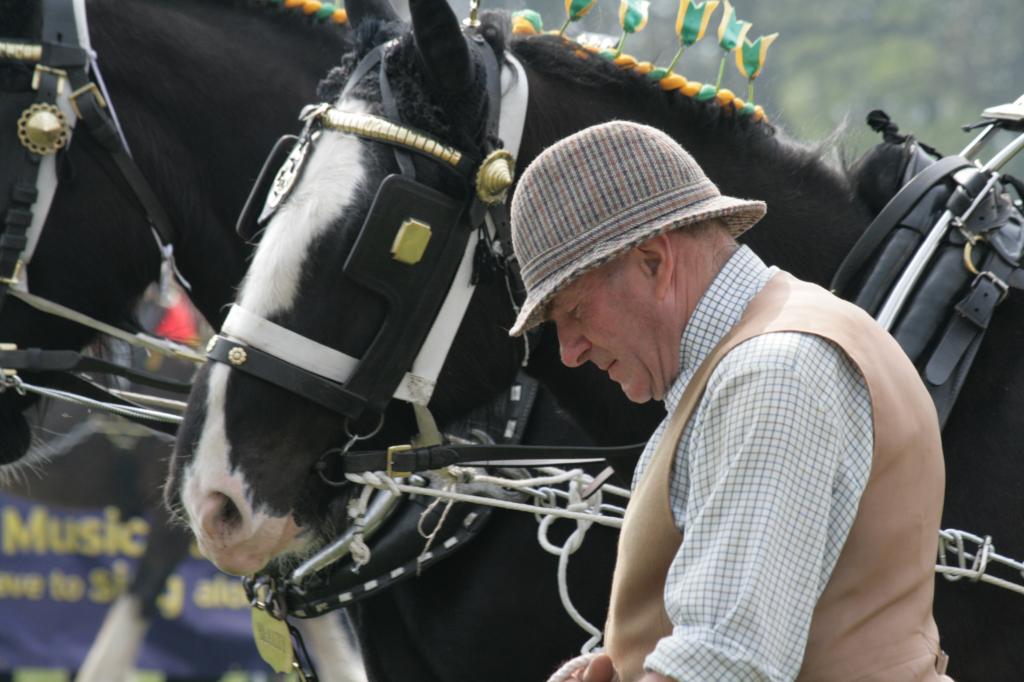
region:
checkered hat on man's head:
[502, 122, 763, 326]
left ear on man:
[632, 226, 677, 297]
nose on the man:
[546, 322, 594, 370]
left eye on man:
[555, 298, 597, 328]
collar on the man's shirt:
[667, 248, 772, 372]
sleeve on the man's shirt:
[654, 331, 882, 680]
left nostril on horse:
[182, 476, 253, 533]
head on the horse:
[152, 3, 552, 589]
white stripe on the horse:
[151, 109, 376, 506]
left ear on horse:
[403, 0, 476, 78]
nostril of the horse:
[193, 491, 258, 537]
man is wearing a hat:
[515, 141, 684, 249]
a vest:
[848, 551, 943, 676]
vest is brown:
[603, 548, 658, 602]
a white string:
[532, 494, 602, 558]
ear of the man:
[638, 238, 683, 286]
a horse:
[6, 20, 225, 296]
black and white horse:
[163, 1, 884, 676]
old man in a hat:
[508, 121, 954, 675]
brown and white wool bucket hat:
[498, 117, 790, 336]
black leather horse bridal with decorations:
[189, 10, 538, 432]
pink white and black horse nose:
[144, 376, 364, 618]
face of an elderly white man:
[543, 228, 728, 403]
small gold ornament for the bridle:
[249, 107, 323, 241]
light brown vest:
[605, 260, 954, 679]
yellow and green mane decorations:
[511, 0, 790, 125]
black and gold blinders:
[330, 165, 470, 355]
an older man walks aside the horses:
[494, 120, 963, 680]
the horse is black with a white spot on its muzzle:
[153, 1, 1021, 681]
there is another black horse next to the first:
[0, 3, 369, 453]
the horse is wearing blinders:
[208, 131, 458, 303]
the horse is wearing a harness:
[175, 109, 1021, 618]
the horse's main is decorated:
[495, 3, 853, 188]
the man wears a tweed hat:
[489, 117, 769, 333]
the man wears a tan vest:
[598, 273, 947, 678]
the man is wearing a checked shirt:
[636, 244, 875, 675]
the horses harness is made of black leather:
[225, 10, 1022, 624]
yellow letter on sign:
[0, 501, 49, 562]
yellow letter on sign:
[45, 507, 80, 572]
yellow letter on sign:
[74, 513, 107, 562]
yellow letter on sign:
[99, 504, 120, 561]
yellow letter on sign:
[118, 510, 148, 559]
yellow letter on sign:
[191, 574, 217, 617]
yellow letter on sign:
[216, 571, 230, 610]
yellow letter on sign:
[222, 576, 252, 612]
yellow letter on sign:
[111, 555, 131, 590]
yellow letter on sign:
[88, 565, 117, 607]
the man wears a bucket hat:
[478, 117, 963, 681]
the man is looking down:
[491, 120, 963, 680]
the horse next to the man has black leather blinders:
[232, 130, 464, 326]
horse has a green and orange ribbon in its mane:
[581, 3, 779, 134]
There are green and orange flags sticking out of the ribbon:
[557, 4, 772, 94]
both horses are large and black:
[2, 3, 1021, 680]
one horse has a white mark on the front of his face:
[170, 99, 366, 562]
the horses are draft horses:
[0, 1, 1021, 681]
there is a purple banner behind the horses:
[2, 504, 309, 681]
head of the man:
[432, 80, 826, 388]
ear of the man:
[609, 224, 704, 314]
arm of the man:
[588, 320, 873, 668]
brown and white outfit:
[524, 281, 980, 667]